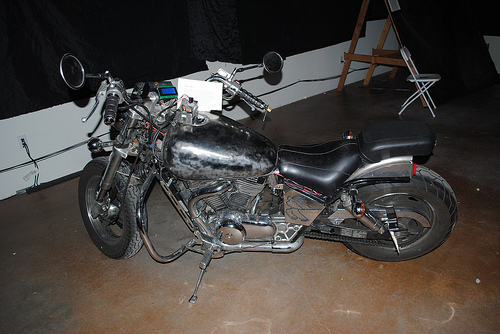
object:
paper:
[177, 78, 224, 111]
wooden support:
[337, 5, 429, 107]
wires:
[120, 105, 155, 162]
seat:
[278, 140, 360, 196]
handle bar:
[104, 93, 120, 126]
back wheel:
[329, 164, 459, 262]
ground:
[0, 202, 452, 334]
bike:
[59, 53, 458, 304]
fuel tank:
[163, 112, 277, 180]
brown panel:
[283, 189, 325, 226]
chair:
[398, 46, 441, 117]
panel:
[3, 36, 388, 201]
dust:
[93, 154, 144, 259]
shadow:
[237, 72, 287, 85]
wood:
[2, 30, 384, 200]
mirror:
[265, 53, 282, 72]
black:
[281, 145, 366, 172]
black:
[363, 117, 425, 154]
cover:
[164, 112, 278, 180]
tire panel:
[344, 155, 414, 183]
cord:
[23, 140, 40, 186]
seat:
[407, 73, 442, 82]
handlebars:
[235, 88, 267, 110]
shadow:
[72, 94, 90, 104]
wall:
[0, 0, 401, 199]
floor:
[0, 68, 485, 329]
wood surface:
[383, 0, 485, 105]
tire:
[78, 156, 149, 259]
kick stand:
[189, 248, 213, 303]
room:
[2, 1, 485, 332]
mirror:
[63, 56, 84, 86]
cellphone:
[157, 85, 178, 99]